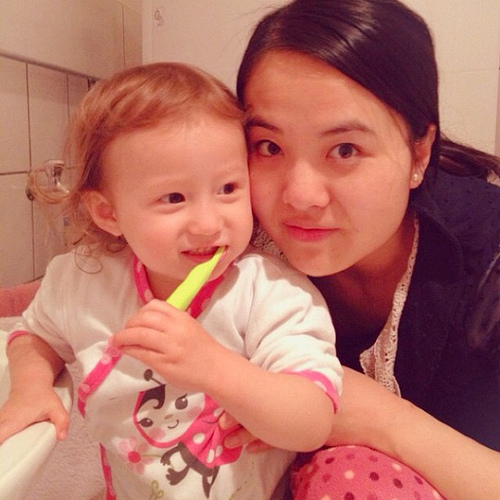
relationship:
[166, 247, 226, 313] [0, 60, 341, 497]
brush used by child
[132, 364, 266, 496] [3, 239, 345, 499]
ladybug character on clothing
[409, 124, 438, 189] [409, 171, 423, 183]
ear with earring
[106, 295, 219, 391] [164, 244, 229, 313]
child's hand holding toothbrush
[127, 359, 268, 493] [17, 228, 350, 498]
picture on shirt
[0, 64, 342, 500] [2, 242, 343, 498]
baby wearing clothing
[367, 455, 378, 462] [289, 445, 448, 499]
polka dot on pants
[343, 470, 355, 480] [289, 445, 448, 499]
polka dot on pants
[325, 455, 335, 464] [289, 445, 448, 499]
polka dot on pants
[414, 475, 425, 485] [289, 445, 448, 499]
polka dot on pants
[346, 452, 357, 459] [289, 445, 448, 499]
polka dot on pants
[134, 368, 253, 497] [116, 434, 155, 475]
lady bug wearing flower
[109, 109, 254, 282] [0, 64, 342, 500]
face of baby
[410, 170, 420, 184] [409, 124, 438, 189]
earring in ear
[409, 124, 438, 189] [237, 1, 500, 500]
ear of lady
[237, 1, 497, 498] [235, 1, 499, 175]
lady has hair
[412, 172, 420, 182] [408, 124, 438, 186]
earring in ear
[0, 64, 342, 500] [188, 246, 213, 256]
baby has baby teeth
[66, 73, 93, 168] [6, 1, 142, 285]
tile on wall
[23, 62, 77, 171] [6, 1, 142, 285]
tile on wall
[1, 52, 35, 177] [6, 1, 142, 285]
tile on wall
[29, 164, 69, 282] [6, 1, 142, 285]
tile on wall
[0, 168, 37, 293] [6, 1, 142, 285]
tile on wall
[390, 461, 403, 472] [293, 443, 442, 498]
polka dots on pants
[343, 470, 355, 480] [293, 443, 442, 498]
polka dot on pants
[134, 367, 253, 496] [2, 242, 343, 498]
lady bug on clothing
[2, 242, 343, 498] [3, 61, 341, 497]
clothing of baby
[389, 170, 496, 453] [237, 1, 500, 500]
blazer on lady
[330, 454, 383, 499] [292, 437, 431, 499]
polka dot on baby pants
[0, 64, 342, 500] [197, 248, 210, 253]
baby brushing baby teeth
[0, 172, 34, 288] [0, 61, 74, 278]
tile on wall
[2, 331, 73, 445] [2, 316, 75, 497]
hand on bathtub rim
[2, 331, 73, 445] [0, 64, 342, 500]
hand of baby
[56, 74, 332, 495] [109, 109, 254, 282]
baby has face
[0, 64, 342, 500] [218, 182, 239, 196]
baby has eye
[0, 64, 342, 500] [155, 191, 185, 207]
baby has eye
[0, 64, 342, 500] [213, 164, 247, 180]
baby has eyebrow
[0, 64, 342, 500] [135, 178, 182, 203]
baby has eyebrow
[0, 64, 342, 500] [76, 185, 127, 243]
baby has right ear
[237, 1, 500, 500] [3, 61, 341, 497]
lady next to baby